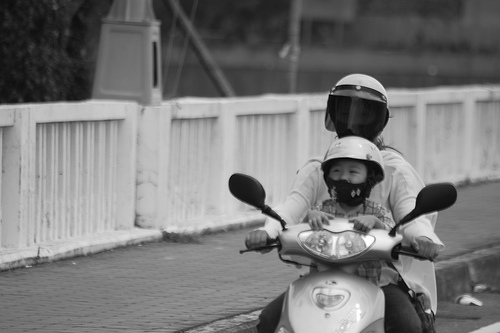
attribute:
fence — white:
[4, 53, 282, 285]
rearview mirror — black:
[393, 181, 465, 234]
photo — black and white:
[4, 2, 487, 330]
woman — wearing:
[242, 76, 438, 323]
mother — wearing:
[245, 72, 438, 309]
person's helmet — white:
[328, 75, 383, 115]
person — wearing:
[243, 71, 445, 317]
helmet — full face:
[321, 70, 391, 143]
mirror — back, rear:
[181, 142, 341, 274]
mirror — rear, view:
[388, 181, 458, 236]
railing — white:
[3, 86, 498, 271]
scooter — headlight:
[229, 171, 444, 329]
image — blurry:
[0, 0, 120, 96]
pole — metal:
[99, 9, 164, 103]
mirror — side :
[413, 182, 468, 213]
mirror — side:
[230, 173, 271, 213]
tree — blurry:
[6, 1, 91, 98]